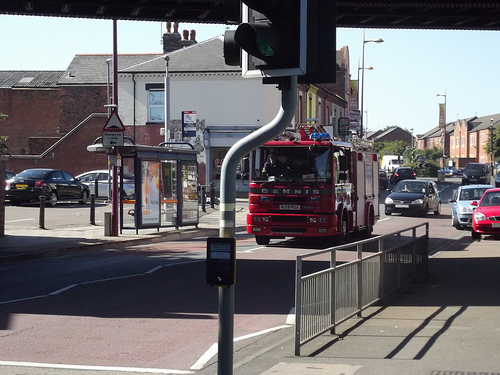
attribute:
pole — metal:
[212, 77, 303, 367]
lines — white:
[3, 255, 184, 307]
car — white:
[75, 162, 140, 201]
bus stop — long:
[88, 134, 200, 233]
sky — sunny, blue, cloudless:
[0, 15, 499, 135]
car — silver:
[448, 181, 493, 232]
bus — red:
[237, 130, 397, 245]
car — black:
[383, 178, 439, 215]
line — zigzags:
[8, 241, 297, 326]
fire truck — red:
[237, 135, 380, 247]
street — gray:
[8, 206, 498, 373]